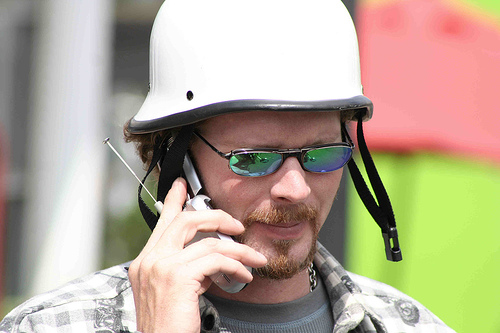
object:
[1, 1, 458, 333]
person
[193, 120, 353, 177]
glasses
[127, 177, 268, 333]
hand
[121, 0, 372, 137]
helmet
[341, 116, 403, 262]
strap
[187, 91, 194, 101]
dot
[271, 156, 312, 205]
nose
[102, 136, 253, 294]
phone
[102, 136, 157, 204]
antenna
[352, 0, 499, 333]
wall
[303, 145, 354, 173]
lens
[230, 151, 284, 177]
lens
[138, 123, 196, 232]
strap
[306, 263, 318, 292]
chain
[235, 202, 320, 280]
facial hair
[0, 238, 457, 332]
shirt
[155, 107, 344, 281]
head